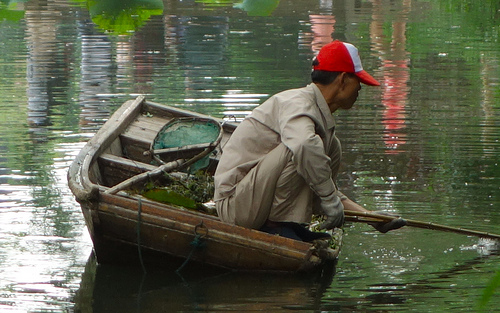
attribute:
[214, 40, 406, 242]
man — asian, fishing, sitting, fishig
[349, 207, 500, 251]
net — for fishing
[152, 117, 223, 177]
net — blue, spare, for fishing, green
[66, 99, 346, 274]
boat — small, brown, wooden, leaning, ragged, for fishing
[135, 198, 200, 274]
rope — blue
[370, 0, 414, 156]
reflection — red, of womam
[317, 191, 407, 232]
gloves — dirty, white, gre, for work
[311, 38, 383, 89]
baseball cap — red, white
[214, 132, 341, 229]
pants — khaki, grey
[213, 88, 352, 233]
suit — tan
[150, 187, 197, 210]
net — green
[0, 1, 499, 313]
water — calm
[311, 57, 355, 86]
hair — dark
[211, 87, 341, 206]
shirt — grey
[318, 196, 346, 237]
glove — white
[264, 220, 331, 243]
shoes — blue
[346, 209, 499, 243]
fishing rod — wooden, for fishing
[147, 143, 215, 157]
stick — wooden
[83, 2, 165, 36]
leaf — green, moist